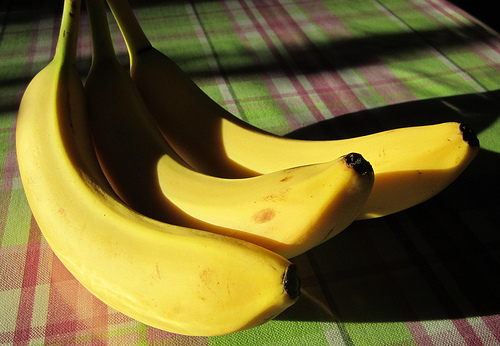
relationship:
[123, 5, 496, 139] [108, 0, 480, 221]
table under banana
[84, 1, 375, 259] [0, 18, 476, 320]
banana on center banana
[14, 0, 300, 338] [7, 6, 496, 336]
banana on table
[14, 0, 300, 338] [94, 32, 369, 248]
banana on banana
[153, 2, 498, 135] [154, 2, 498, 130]
table has many stripes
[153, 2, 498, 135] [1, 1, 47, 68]
table has many stripes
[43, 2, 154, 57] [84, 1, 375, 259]
stem on banana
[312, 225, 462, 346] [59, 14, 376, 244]
shadow from banana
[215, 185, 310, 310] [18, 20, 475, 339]
scratch on a banana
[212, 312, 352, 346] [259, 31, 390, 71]
stripes on table cloth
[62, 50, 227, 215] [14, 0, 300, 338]
shadow on a banana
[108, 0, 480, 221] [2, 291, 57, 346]
banana on a tablecloth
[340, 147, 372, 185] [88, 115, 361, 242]
tip of banana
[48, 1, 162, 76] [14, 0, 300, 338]
stems of banana